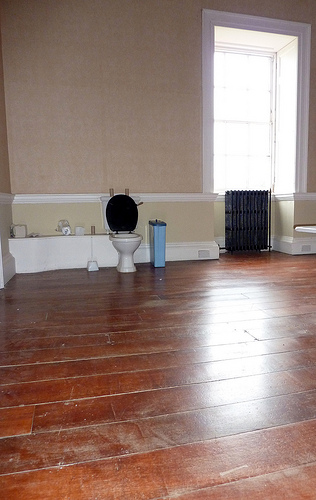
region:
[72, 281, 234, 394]
brown wooden floor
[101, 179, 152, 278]
white toilet with a black toilet seat cover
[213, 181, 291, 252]
silver and black radiator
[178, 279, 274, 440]
light reflecting on woo floor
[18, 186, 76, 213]
white molding on wall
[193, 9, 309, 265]
large tall window with white wooden frame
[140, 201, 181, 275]
blue trash can with black lid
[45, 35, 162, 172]
tan wall paper on walls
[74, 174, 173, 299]
toilet seat in empty room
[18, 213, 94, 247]
items on shelf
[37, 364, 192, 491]
the floors are wooden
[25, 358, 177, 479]
the floors are dirty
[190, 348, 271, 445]
the light is on floor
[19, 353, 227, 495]
the floor is brown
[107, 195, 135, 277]
the toilet is white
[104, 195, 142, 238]
the lid is black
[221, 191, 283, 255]
the heater is black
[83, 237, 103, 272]
toilet cleaner is white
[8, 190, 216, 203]
the molding is white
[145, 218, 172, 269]
the bin is blue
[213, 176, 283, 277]
this is a water heater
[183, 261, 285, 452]
this is a sun glare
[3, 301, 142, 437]
this is the wooden floor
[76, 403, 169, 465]
dust on wooden floor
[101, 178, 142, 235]
black porcelain toilet lid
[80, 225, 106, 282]
white plastic toilet brush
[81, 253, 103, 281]
a toilet brush holder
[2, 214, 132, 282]
a white bath tub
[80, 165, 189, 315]
a white porcelain toilet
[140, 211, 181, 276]
a blue trash can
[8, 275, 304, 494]
Floor is made out of hard wood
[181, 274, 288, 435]
Light is reflecting off the hard wood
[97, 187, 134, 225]
Top of the toilet is black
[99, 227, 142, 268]
Toilet bowl is white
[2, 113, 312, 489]
Photo was taken indoors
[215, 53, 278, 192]
Photo was taken in the daytime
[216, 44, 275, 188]
Window is letting in sunlight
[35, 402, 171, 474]
The floor is dusty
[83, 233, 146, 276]
Toilet cleaner is by toilet bowl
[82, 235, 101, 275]
Toilet cleaner is white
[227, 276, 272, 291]
floor made of wood.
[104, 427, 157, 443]
dust on the floor.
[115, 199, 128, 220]
black toilet seat.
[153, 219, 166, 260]
waste basket near toilet.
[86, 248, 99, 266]
toilet cleaner near toilet.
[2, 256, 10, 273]
white trim on wall.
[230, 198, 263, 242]
black radiator near window.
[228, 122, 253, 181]
window above the radiator.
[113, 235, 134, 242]
white bowl of toilet.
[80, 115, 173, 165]
blank wall above the toilet.